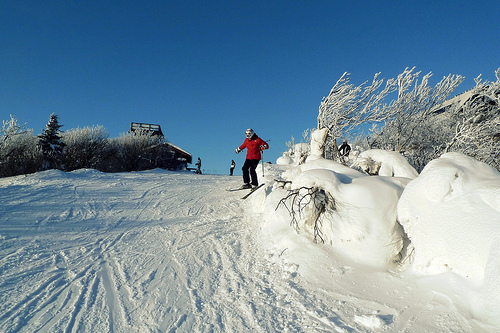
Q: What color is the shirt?
A: Red.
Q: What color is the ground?
A: White.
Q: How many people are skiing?
A: One.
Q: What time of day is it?
A: Daytime.